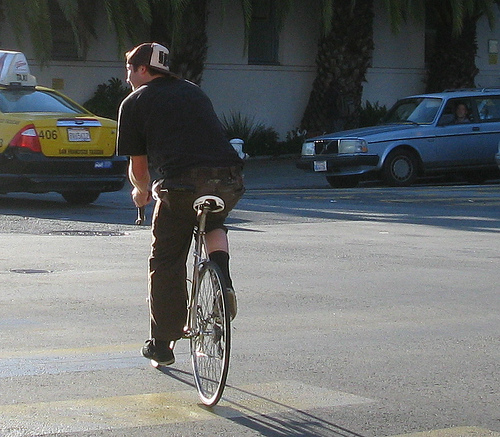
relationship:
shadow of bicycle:
[157, 363, 365, 437] [132, 166, 236, 407]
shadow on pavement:
[157, 363, 365, 437] [1, 185, 499, 436]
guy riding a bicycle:
[111, 40, 248, 369] [132, 166, 236, 407]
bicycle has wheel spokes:
[132, 166, 236, 407] [190, 274, 225, 399]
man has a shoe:
[111, 40, 248, 369] [140, 339, 177, 368]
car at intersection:
[295, 85, 500, 188] [1, 195, 499, 437]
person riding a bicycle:
[111, 40, 248, 369] [132, 166, 236, 407]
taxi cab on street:
[0, 45, 130, 207] [1, 195, 499, 437]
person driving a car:
[452, 102, 471, 124] [295, 85, 500, 188]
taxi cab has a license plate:
[0, 45, 130, 207] [66, 124, 92, 143]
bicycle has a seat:
[132, 166, 236, 407] [191, 193, 225, 215]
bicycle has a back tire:
[132, 166, 236, 407] [189, 256, 234, 409]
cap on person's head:
[123, 41, 185, 79] [119, 38, 175, 92]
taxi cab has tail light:
[0, 45, 130, 207] [12, 122, 43, 155]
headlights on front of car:
[301, 138, 369, 157] [295, 85, 500, 188]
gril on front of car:
[310, 140, 340, 154] [295, 85, 500, 188]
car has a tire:
[295, 85, 500, 188] [384, 151, 414, 185]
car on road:
[295, 85, 500, 188] [1, 195, 499, 437]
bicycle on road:
[132, 166, 236, 407] [1, 195, 499, 437]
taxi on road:
[0, 45, 130, 207] [1, 195, 499, 437]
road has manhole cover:
[1, 195, 499, 437] [47, 227, 126, 239]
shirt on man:
[111, 75, 242, 169] [111, 40, 248, 369]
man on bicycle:
[111, 40, 248, 369] [132, 166, 236, 407]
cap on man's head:
[123, 41, 185, 79] [119, 38, 175, 92]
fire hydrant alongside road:
[228, 136, 250, 181] [1, 195, 499, 437]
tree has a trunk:
[268, 1, 412, 135] [300, 0, 377, 132]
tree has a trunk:
[106, 0, 215, 88] [152, 1, 209, 87]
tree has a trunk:
[401, 0, 496, 96] [423, 1, 481, 93]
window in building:
[46, 2, 86, 60] [2, 1, 499, 141]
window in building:
[246, 0, 281, 67] [2, 1, 499, 141]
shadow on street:
[157, 363, 365, 437] [1, 195, 499, 437]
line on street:
[0, 374, 377, 437] [1, 195, 499, 437]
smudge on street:
[120, 393, 209, 424] [1, 195, 499, 437]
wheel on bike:
[189, 256, 234, 409] [132, 166, 236, 407]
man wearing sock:
[111, 40, 248, 369] [208, 248, 234, 287]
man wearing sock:
[111, 40, 248, 369] [153, 337, 169, 350]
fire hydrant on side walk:
[228, 136, 250, 181] [123, 156, 328, 193]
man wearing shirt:
[111, 40, 248, 369] [111, 75, 242, 169]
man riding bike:
[111, 40, 248, 369] [132, 166, 236, 407]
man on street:
[111, 40, 248, 369] [1, 195, 499, 437]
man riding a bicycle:
[111, 40, 248, 369] [132, 166, 236, 407]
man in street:
[111, 40, 248, 369] [1, 195, 499, 437]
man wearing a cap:
[111, 40, 248, 369] [123, 41, 185, 79]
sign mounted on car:
[0, 46, 37, 89] [0, 45, 130, 207]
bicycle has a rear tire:
[132, 166, 236, 407] [189, 256, 234, 409]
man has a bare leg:
[111, 40, 248, 369] [204, 227, 230, 256]